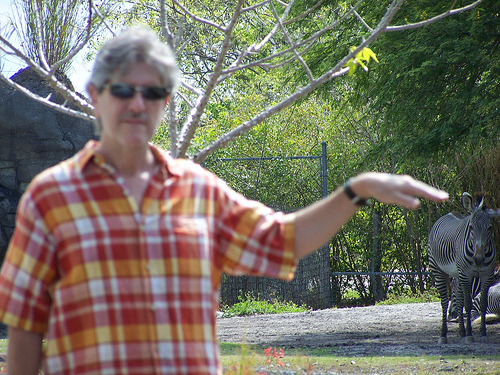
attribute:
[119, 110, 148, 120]
mustache — white, black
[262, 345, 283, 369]
flowers — red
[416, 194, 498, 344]
zebra — grey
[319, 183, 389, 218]
watchband — black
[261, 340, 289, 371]
flowers — red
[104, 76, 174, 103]
sunglasses — dark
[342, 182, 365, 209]
watch band — black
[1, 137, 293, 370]
orange-red shirt — red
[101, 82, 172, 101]
glasses — black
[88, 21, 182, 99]
hair — grey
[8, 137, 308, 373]
shirt — orange, checkered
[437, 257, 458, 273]
belly — white